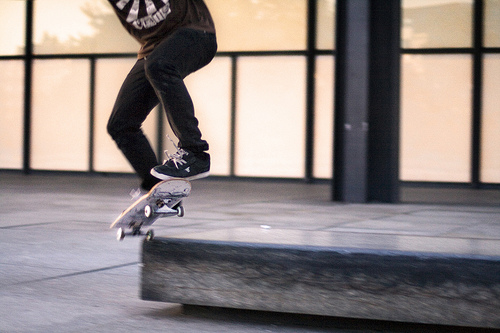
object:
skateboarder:
[105, 0, 219, 240]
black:
[191, 155, 206, 166]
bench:
[140, 223, 498, 328]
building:
[0, 1, 499, 189]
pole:
[335, 0, 399, 205]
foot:
[151, 150, 213, 180]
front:
[151, 176, 192, 202]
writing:
[126, 7, 173, 30]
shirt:
[96, 0, 216, 59]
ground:
[0, 205, 116, 293]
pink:
[401, 55, 469, 178]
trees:
[32, 1, 108, 59]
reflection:
[401, 0, 472, 46]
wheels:
[116, 227, 126, 241]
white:
[171, 154, 189, 164]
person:
[105, 0, 217, 211]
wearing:
[147, 150, 212, 184]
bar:
[464, 0, 486, 191]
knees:
[95, 112, 127, 142]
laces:
[164, 134, 189, 171]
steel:
[344, 77, 384, 187]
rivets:
[341, 121, 355, 131]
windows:
[33, 61, 90, 172]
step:
[139, 229, 287, 311]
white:
[178, 204, 185, 218]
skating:
[108, 142, 213, 239]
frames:
[469, 0, 483, 49]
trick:
[105, 1, 213, 240]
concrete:
[392, 200, 485, 232]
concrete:
[141, 216, 499, 330]